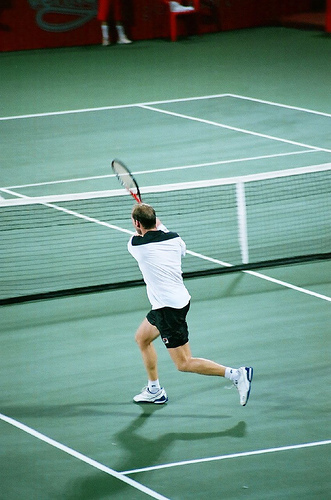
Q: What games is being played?
A: Tennis.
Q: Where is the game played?
A: Tennis court.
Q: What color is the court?
A: Green.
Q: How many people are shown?
A: Two.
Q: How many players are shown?
A: One.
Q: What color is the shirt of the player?
A: White.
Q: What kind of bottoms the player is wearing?
A: Shorts.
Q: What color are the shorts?
A: Black.